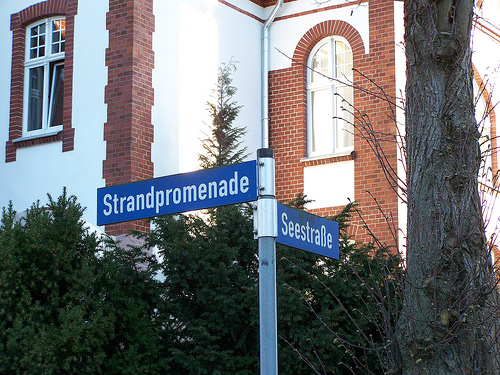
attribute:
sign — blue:
[95, 160, 257, 228]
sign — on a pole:
[254, 147, 340, 375]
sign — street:
[251, 197, 264, 242]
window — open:
[24, 13, 71, 134]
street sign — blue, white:
[91, 159, 341, 271]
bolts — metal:
[246, 158, 271, 242]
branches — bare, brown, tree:
[285, 25, 425, 215]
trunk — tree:
[380, 5, 472, 373]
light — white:
[177, 7, 257, 211]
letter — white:
[320, 224, 338, 256]